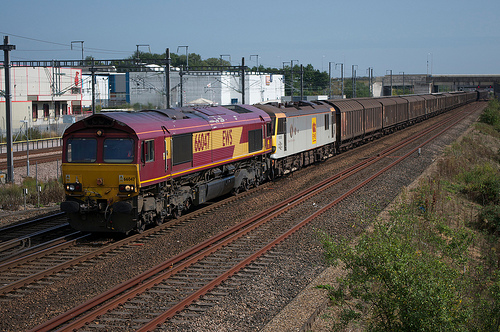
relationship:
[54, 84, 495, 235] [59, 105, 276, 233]
train has engine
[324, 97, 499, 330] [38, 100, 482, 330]
foliage bounding tracks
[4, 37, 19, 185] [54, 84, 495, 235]
pole near train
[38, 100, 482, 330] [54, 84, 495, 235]
tracks for train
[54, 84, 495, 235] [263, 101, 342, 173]
train has secondary engine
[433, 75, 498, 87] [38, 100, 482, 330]
bridge over tracks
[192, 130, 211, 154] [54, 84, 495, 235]
numbers on train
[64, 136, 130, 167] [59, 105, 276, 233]
windows are for engine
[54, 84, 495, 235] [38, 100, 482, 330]
train on tracks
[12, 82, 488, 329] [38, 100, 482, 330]
railroad has tracks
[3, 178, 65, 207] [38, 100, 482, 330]
bushes on side of tracks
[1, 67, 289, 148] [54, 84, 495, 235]
building next to train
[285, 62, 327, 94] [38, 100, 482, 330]
trees near tracks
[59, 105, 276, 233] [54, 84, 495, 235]
engine for train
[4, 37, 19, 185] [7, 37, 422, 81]
pole with wires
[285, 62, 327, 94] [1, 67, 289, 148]
trees far from building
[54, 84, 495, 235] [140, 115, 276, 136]
train has stripe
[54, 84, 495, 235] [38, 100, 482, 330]
train has tracks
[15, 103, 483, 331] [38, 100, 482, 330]
gravel on tracks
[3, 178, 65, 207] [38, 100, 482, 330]
bushes alongside tracks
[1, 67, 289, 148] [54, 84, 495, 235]
building behind train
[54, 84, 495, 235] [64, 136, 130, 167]
train has windows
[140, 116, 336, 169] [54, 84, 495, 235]
side windows on train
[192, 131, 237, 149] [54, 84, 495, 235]
writing on train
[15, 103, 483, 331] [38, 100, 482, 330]
gravel by tracks